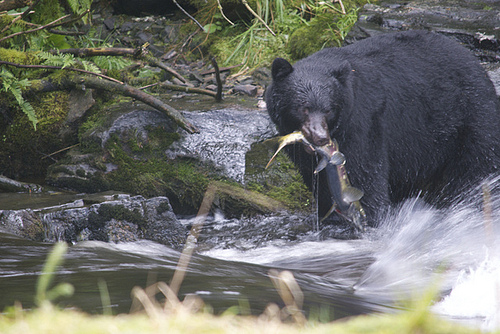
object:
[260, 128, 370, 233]
fish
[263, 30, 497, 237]
bear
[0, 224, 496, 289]
water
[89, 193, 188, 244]
rocks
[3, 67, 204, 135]
branches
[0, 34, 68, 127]
roots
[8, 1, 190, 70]
back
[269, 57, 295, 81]
two ears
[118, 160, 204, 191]
moss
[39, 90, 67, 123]
grass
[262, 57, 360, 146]
head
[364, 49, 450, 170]
fur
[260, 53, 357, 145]
face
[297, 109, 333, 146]
snout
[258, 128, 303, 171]
tail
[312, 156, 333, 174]
fin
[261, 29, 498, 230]
black